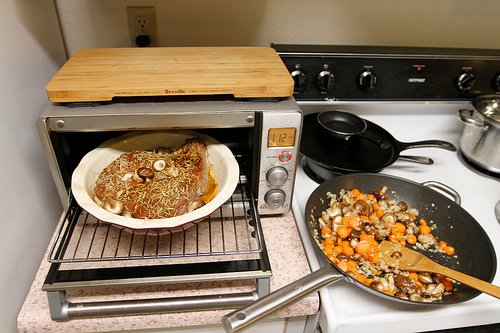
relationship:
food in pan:
[327, 194, 450, 293] [302, 168, 497, 316]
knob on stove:
[354, 70, 381, 90] [271, 38, 499, 325]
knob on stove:
[311, 66, 328, 94] [271, 38, 499, 325]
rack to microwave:
[50, 177, 264, 264] [29, 104, 304, 247]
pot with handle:
[457, 90, 500, 180] [453, 102, 487, 136]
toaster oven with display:
[29, 104, 304, 247] [267, 126, 297, 149]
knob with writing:
[354, 70, 381, 90] [361, 64, 376, 71]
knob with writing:
[457, 71, 481, 93] [460, 66, 474, 71]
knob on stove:
[457, 71, 481, 93] [271, 38, 499, 325]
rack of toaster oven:
[50, 177, 264, 264] [29, 104, 304, 247]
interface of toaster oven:
[267, 126, 297, 149] [29, 104, 304, 247]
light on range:
[415, 66, 424, 72] [271, 38, 499, 325]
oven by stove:
[36, 42, 319, 300] [271, 38, 499, 325]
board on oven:
[45, 45, 298, 105] [36, 42, 319, 300]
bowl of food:
[65, 134, 250, 242] [99, 132, 217, 219]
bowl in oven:
[65, 134, 250, 242] [36, 42, 319, 300]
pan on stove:
[302, 168, 497, 316] [271, 38, 499, 325]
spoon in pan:
[374, 237, 499, 309] [302, 168, 497, 316]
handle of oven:
[44, 288, 284, 312] [36, 42, 319, 300]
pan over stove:
[302, 168, 497, 316] [271, 38, 499, 325]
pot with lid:
[457, 90, 500, 180] [471, 97, 499, 125]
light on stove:
[415, 66, 424, 72] [271, 38, 499, 325]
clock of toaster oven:
[267, 126, 297, 149] [29, 104, 304, 247]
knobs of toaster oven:
[264, 166, 291, 212] [29, 104, 304, 247]